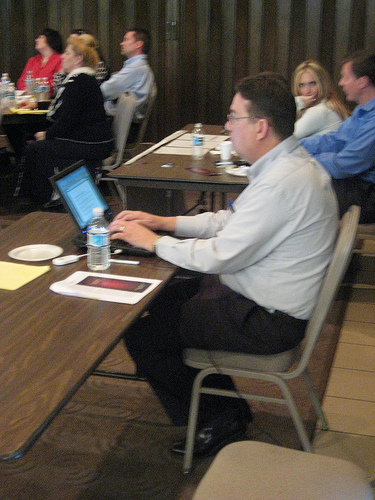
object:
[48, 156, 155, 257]
laptop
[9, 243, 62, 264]
plate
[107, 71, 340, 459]
man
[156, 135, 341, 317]
shirt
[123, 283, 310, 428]
pants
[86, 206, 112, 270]
bottle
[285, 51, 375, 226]
people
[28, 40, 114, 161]
people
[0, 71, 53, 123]
table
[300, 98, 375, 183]
shirt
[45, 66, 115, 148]
sweater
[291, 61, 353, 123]
hair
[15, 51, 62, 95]
shirt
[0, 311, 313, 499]
floor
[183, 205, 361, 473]
chair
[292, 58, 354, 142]
woman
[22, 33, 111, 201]
woman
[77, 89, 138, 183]
chair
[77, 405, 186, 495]
carpet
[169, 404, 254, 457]
shoes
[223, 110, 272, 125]
eyeglasses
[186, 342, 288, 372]
cushion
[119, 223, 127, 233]
ring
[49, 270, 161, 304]
paper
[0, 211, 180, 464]
table